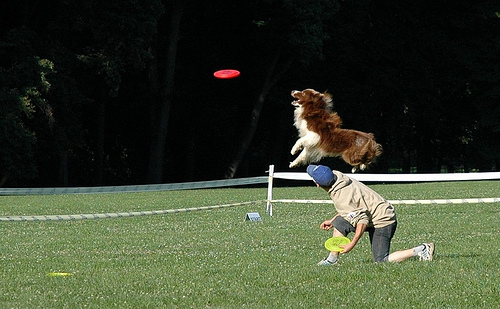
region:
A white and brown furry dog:
[280, 80, 390, 178]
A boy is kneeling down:
[295, 156, 437, 268]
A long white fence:
[0, 160, 496, 227]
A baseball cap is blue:
[300, 155, 335, 190]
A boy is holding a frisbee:
[300, 156, 376, 253]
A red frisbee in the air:
[210, 60, 242, 82]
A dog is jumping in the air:
[280, 80, 385, 176]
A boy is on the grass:
[260, 160, 480, 296]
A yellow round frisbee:
[321, 230, 356, 253]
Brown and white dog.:
[286, 88, 383, 173]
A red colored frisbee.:
[213, 68, 241, 80]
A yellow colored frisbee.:
[323, 235, 352, 252]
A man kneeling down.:
[306, 163, 436, 268]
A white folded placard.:
[244, 211, 262, 223]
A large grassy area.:
[0, 181, 499, 307]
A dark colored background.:
[0, 0, 499, 189]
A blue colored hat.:
[306, 163, 336, 185]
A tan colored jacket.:
[327, 170, 399, 227]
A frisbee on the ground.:
[46, 268, 76, 279]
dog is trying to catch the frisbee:
[205, 60, 380, 165]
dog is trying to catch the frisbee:
[208, 60, 389, 174]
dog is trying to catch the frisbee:
[192, 51, 392, 182]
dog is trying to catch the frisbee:
[197, 42, 392, 174]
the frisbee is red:
[189, 59, 259, 87]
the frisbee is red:
[200, 53, 252, 93]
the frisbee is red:
[206, 47, 243, 92]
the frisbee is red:
[203, 54, 258, 99]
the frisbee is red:
[203, 55, 243, 89]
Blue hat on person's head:
[301, 155, 334, 190]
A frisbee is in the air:
[205, 60, 245, 82]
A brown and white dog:
[285, 80, 385, 172]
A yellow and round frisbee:
[320, 231, 355, 252]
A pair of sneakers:
[311, 237, 436, 264]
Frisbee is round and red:
[207, 57, 242, 83]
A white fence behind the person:
[0, 160, 495, 225]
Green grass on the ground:
[0, 180, 495, 305]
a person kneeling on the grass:
[305, 160, 455, 271]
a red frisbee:
[205, 65, 242, 80]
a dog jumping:
[285, 80, 380, 155]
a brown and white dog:
[280, 80, 375, 155]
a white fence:
[265, 165, 495, 180]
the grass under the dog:
[5, 190, 495, 300]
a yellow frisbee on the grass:
[45, 260, 75, 275]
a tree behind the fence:
[15, 46, 65, 166]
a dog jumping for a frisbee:
[195, 55, 380, 180]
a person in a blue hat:
[296, 152, 421, 287]